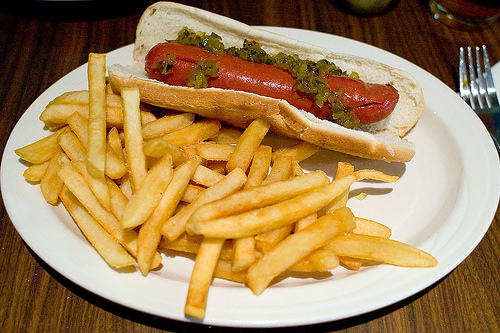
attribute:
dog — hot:
[102, 8, 439, 175]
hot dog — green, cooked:
[142, 33, 409, 124]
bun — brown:
[98, 1, 427, 169]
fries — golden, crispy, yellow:
[19, 98, 436, 320]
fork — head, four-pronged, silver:
[454, 38, 500, 117]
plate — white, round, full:
[6, 19, 499, 333]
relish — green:
[158, 23, 369, 123]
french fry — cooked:
[176, 233, 225, 318]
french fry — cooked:
[338, 234, 439, 273]